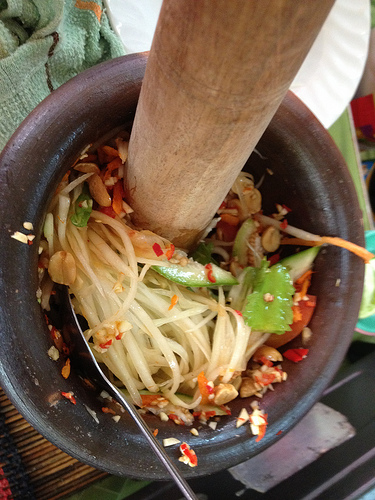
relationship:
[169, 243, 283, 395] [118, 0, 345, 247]
spices with a mortar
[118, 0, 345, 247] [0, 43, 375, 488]
mortar and pestle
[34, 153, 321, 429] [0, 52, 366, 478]
ingredients with mortar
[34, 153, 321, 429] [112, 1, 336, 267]
ingredients and pestle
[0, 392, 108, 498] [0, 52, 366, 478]
bamboo placemat with mortar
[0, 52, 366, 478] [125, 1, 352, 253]
mortar and pestle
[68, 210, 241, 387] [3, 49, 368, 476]
noodles in bowl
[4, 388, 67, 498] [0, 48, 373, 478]
table under cup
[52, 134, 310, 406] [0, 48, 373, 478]
mixed food in cup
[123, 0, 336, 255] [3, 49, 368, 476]
stick in bowl